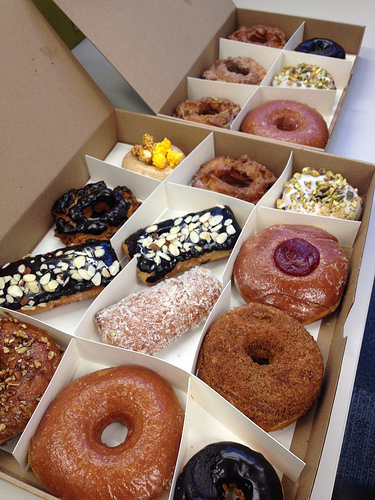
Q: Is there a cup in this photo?
A: No, there are no cups.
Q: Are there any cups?
A: No, there are no cups.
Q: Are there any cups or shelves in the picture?
A: No, there are no cups or shelves.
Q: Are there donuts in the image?
A: Yes, there is a donut.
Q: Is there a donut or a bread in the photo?
A: Yes, there is a donut.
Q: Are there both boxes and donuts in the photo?
A: Yes, there are both a donut and a box.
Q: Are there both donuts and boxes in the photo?
A: Yes, there are both a donut and a box.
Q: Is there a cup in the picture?
A: No, there are no cups.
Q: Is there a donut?
A: Yes, there is a donut.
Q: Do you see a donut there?
A: Yes, there is a donut.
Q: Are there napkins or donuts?
A: Yes, there is a donut.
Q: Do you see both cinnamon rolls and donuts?
A: No, there is a donut but no cinnamon rolls.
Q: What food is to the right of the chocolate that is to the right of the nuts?
A: The food is a donut.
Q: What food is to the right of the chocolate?
A: The food is a donut.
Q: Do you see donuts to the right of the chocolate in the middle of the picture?
A: Yes, there is a donut to the right of the chocolate.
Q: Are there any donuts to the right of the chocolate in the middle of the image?
A: Yes, there is a donut to the right of the chocolate.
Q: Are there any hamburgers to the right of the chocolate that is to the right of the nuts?
A: No, there is a donut to the right of the chocolate.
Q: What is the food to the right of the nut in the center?
A: The food is a donut.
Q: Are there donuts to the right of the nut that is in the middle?
A: Yes, there is a donut to the right of the nut.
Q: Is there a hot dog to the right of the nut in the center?
A: No, there is a donut to the right of the nut.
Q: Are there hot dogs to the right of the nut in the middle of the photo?
A: No, there is a donut to the right of the nut.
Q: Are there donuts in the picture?
A: Yes, there is a donut.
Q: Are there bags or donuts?
A: Yes, there is a donut.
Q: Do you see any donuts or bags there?
A: Yes, there is a donut.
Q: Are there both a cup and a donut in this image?
A: No, there is a donut but no cups.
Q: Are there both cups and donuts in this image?
A: No, there is a donut but no cups.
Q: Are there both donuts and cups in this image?
A: No, there is a donut but no cups.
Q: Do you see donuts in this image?
A: Yes, there is a donut.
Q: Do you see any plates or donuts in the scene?
A: Yes, there is a donut.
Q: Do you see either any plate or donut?
A: Yes, there is a donut.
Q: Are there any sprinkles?
A: No, there are no sprinkles.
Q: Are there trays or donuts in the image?
A: Yes, there is a donut.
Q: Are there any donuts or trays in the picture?
A: Yes, there is a donut.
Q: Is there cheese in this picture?
A: No, there is no cheese.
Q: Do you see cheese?
A: No, there is no cheese.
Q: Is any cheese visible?
A: No, there is no cheese.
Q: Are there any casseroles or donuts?
A: Yes, there is a donut.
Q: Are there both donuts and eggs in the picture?
A: No, there is a donut but no eggs.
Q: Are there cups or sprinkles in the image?
A: No, there are no cups or sprinkles.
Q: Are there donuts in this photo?
A: Yes, there is a donut.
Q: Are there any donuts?
A: Yes, there is a donut.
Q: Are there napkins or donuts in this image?
A: Yes, there is a donut.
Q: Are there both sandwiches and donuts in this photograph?
A: No, there is a donut but no sandwiches.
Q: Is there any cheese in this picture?
A: No, there is no cheese.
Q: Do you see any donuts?
A: Yes, there is a donut.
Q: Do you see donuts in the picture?
A: Yes, there is a donut.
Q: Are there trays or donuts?
A: Yes, there is a donut.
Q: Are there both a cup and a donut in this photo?
A: No, there is a donut but no cups.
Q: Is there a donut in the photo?
A: Yes, there is a donut.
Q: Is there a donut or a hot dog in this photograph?
A: Yes, there is a donut.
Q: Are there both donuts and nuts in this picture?
A: Yes, there are both a donut and a nut.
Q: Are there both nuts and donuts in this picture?
A: Yes, there are both a donut and a nut.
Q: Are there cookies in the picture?
A: No, there are no cookies.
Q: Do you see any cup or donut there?
A: Yes, there is a donut.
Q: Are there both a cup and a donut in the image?
A: No, there is a donut but no cups.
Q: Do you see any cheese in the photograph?
A: No, there is no cheese.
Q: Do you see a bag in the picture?
A: No, there are no bags.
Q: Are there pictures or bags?
A: No, there are no bags or pictures.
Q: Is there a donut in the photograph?
A: Yes, there is a donut.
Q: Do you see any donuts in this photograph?
A: Yes, there is a donut.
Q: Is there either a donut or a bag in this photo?
A: Yes, there is a donut.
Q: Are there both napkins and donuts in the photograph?
A: No, there is a donut but no napkins.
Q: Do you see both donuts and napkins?
A: No, there is a donut but no napkins.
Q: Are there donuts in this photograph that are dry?
A: Yes, there is a dry donut.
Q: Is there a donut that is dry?
A: Yes, there is a donut that is dry.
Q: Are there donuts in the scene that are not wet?
A: Yes, there is a dry donut.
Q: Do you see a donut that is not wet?
A: Yes, there is a dry donut.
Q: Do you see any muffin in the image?
A: No, there are no muffins.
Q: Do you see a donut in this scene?
A: Yes, there is a donut.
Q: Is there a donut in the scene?
A: Yes, there is a donut.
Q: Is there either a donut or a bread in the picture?
A: Yes, there is a donut.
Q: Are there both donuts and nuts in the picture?
A: Yes, there are both a donut and a nut.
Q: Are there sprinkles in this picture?
A: No, there are no sprinkles.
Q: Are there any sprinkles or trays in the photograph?
A: No, there are no sprinkles or trays.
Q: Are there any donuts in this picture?
A: Yes, there is a donut.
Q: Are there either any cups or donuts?
A: Yes, there is a donut.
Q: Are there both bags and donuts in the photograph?
A: No, there is a donut but no bags.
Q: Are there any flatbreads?
A: No, there are no flatbreads.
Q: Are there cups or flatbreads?
A: No, there are no flatbreads or cups.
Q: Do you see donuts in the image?
A: Yes, there is a donut.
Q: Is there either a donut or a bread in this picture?
A: Yes, there is a donut.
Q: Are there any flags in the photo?
A: No, there are no flags.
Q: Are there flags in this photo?
A: No, there are no flags.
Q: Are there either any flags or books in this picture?
A: No, there are no flags or books.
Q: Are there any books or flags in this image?
A: No, there are no flags or books.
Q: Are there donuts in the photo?
A: Yes, there is a donut.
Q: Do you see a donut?
A: Yes, there is a donut.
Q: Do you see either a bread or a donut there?
A: Yes, there is a donut.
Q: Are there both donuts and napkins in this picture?
A: No, there is a donut but no napkins.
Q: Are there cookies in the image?
A: No, there are no cookies.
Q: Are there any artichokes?
A: No, there are no artichokes.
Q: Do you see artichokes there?
A: No, there are no artichokes.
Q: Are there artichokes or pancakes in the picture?
A: No, there are no artichokes or pancakes.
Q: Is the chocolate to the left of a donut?
A: Yes, the chocolate is to the left of a donut.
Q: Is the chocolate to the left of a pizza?
A: No, the chocolate is to the left of a donut.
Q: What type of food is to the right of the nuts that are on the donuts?
A: The food is chocolate.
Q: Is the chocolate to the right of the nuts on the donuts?
A: Yes, the chocolate is to the right of the nuts.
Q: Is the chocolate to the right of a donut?
A: Yes, the chocolate is to the right of a donut.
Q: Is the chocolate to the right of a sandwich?
A: No, the chocolate is to the right of a donut.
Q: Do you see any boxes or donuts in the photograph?
A: Yes, there is a donut.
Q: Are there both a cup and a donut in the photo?
A: No, there is a donut but no cups.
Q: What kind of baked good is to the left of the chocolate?
A: The food is a donut.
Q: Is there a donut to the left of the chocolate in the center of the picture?
A: Yes, there is a donut to the left of the chocolate.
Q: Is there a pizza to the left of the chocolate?
A: No, there is a donut to the left of the chocolate.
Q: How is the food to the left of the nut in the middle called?
A: The food is a donut.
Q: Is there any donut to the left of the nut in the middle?
A: Yes, there is a donut to the left of the nut.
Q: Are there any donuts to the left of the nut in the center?
A: Yes, there is a donut to the left of the nut.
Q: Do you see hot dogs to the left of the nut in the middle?
A: No, there is a donut to the left of the nut.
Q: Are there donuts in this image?
A: Yes, there are donuts.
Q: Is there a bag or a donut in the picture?
A: Yes, there are donuts.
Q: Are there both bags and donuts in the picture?
A: No, there are donuts but no bags.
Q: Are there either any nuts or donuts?
A: Yes, there is a donut.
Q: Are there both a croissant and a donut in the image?
A: No, there is a donut but no croissants.